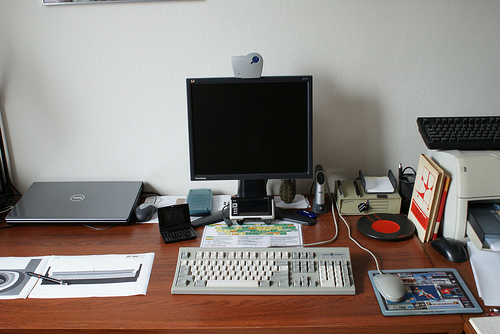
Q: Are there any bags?
A: No, there are no bags.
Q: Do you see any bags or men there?
A: No, there are no bags or men.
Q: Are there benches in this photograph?
A: No, there are no benches.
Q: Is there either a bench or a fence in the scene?
A: No, there are no benches or fences.